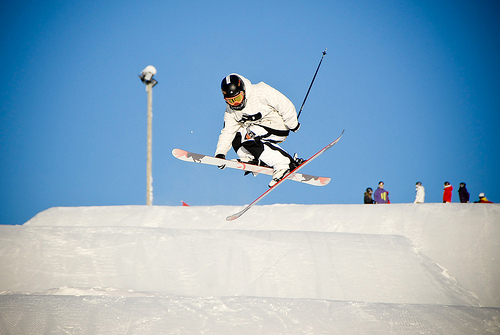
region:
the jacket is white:
[185, 61, 298, 153]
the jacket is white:
[168, 76, 309, 158]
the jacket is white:
[194, 79, 318, 153]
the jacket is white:
[200, 76, 326, 183]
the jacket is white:
[179, 63, 298, 153]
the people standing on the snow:
[339, 156, 492, 213]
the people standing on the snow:
[329, 169, 499, 236]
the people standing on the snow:
[350, 170, 499, 218]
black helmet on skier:
[215, 64, 263, 114]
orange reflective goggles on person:
[211, 93, 260, 110]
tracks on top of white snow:
[124, 276, 266, 325]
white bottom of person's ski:
[171, 138, 281, 197]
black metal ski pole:
[305, 37, 350, 119]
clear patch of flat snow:
[306, 236, 375, 285]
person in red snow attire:
[434, 172, 459, 207]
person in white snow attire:
[408, 169, 431, 214]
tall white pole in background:
[133, 45, 161, 202]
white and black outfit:
[214, 98, 304, 170]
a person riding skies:
[126, 41, 276, 248]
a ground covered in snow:
[293, 241, 403, 333]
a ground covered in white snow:
[260, 208, 405, 333]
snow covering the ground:
[269, 227, 406, 329]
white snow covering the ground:
[282, 218, 427, 330]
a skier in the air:
[166, 36, 407, 238]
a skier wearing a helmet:
[209, 59, 374, 250]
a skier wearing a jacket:
[201, 54, 351, 241]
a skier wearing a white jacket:
[202, 32, 332, 212]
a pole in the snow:
[119, 36, 191, 246]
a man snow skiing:
[166, 16, 345, 256]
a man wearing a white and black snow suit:
[214, 61, 305, 158]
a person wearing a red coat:
[440, 180, 455, 208]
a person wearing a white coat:
[409, 180, 426, 209]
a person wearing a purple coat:
[372, 173, 393, 221]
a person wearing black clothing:
[456, 175, 472, 212]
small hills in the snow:
[33, 204, 411, 301]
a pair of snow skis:
[166, 128, 346, 230]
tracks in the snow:
[10, 279, 396, 324]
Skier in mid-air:
[114, 34, 376, 228]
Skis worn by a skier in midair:
[158, 133, 350, 238]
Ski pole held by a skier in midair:
[176, 45, 336, 140]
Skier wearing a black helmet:
[189, 62, 306, 224]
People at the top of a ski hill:
[319, 57, 474, 305]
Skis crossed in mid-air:
[138, 128, 358, 233]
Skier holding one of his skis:
[159, 66, 264, 183]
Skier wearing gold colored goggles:
[203, 49, 274, 131]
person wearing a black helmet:
[215, 69, 251, 109]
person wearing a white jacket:
[203, 72, 289, 144]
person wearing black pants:
[216, 125, 293, 180]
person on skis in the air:
[162, 130, 354, 223]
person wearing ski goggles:
[214, 84, 247, 106]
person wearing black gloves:
[211, 152, 226, 169]